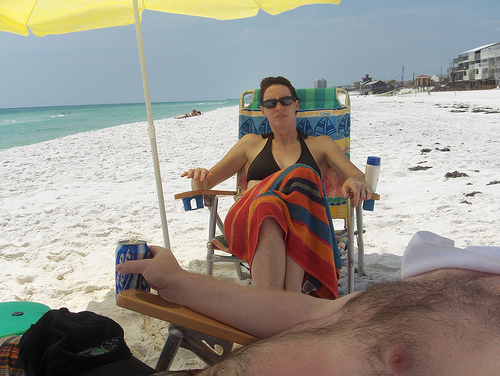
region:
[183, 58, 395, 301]
a woman sitting in a beach chair at the beach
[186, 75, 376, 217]
a woman wearing a bikini top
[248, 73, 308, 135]
a woman wearing black sunglasses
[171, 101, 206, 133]
a person lying on the beach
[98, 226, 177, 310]
a hand holding a budlight beer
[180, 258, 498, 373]
the shirtless chest of a man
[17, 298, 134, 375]
a black baseball cap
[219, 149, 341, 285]
a colorful beach towel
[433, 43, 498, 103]
a building beside the beach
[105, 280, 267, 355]
the arm rest of a chair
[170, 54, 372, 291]
Woman sitting in lounge chair.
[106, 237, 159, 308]
Man holding beer can in hand.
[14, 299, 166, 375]
Black cap lying on man's lap.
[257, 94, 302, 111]
Woman wearing sunglasses over eyes.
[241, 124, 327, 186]
Woman wearing black bathing suit top.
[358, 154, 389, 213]
Sun screen sitting on chair arm.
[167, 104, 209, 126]
People lying on beach.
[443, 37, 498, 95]
Beach house in background.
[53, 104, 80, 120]
People swimming in water.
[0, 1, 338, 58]
An open yellow umbrella.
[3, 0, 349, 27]
a yellow umbrella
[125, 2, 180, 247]
the pole on the umbrella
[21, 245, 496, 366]
a man laying in a chair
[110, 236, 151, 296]
a beer can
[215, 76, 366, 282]
a lady sitting in a chair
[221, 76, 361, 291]
a lady wearing sun glasses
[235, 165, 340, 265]
a towel on the lap of the lady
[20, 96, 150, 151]
water in front of the sand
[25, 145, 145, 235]
sand on the beach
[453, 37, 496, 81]
buildings behind the beach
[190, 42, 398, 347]
this is a woman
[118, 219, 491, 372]
this is a man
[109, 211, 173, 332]
this is a beer can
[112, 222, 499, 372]
man holding a bear can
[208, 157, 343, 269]
this is a towel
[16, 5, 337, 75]
this is an umbrella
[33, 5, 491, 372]
people sitting at the beach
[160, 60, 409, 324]
woman sitting on a chair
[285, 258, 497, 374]
dark hair on the chest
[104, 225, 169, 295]
hand holding a beer can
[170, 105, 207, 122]
person lying on the beach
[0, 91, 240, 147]
light blue body of water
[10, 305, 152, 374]
hat laying on the lap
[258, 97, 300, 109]
sunglasses on the face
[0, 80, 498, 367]
white sand laying on the ground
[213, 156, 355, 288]
stripes on the towel